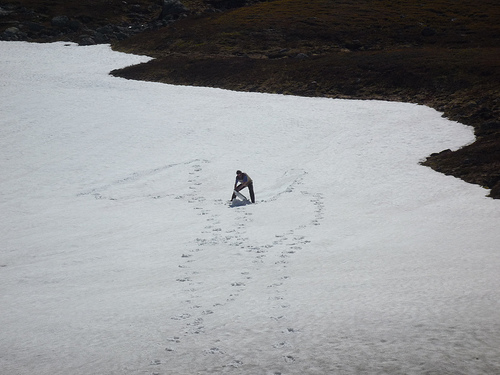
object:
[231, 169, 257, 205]
man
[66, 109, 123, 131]
snow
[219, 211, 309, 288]
tracks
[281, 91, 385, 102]
edge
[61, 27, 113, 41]
boulders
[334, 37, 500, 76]
mountain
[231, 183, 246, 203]
leg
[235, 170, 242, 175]
cap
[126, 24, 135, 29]
lights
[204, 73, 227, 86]
dirt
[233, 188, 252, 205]
skis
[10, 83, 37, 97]
ground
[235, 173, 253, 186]
jacket